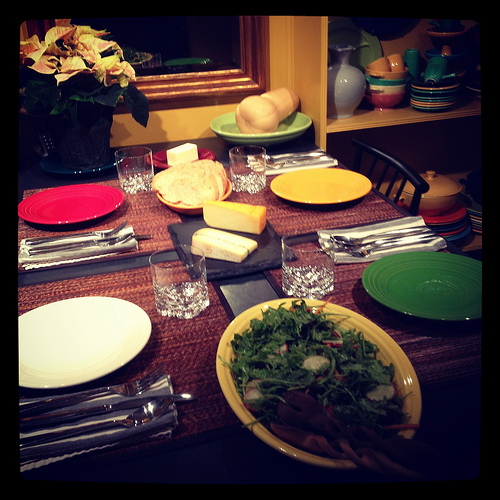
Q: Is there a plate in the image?
A: Yes, there is a plate.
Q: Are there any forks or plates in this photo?
A: Yes, there is a plate.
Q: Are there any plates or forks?
A: Yes, there is a plate.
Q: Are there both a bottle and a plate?
A: No, there is a plate but no bottles.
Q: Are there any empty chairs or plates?
A: Yes, there is an empty plate.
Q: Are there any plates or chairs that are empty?
A: Yes, the plate is empty.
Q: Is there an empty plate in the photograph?
A: Yes, there is an empty plate.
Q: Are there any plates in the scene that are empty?
A: Yes, there is a plate that is empty.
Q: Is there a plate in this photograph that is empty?
A: Yes, there is a plate that is empty.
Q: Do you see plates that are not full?
A: Yes, there is a empty plate.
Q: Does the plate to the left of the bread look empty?
A: Yes, the plate is empty.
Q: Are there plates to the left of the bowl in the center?
A: Yes, there is a plate to the left of the bowl.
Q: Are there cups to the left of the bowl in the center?
A: No, there is a plate to the left of the bowl.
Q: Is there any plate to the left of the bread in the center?
A: Yes, there is a plate to the left of the bread.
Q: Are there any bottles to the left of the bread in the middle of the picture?
A: No, there is a plate to the left of the bread.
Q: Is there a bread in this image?
A: Yes, there is a bread.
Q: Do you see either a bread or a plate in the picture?
A: Yes, there is a bread.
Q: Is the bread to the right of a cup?
A: No, the bread is to the right of the plate.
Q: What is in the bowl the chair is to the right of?
A: The bread is in the bowl.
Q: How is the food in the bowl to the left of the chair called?
A: The food is a bread.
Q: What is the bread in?
A: The bread is in the bowl.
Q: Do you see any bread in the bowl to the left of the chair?
A: Yes, there is a bread in the bowl.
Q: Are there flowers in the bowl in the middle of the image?
A: No, there is a bread in the bowl.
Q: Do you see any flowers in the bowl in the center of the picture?
A: No, there is a bread in the bowl.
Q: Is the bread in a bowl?
A: Yes, the bread is in a bowl.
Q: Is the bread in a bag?
A: No, the bread is in a bowl.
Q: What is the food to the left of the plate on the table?
A: The food is a bread.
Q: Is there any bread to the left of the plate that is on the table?
A: Yes, there is a bread to the left of the plate.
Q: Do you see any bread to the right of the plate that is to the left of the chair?
A: No, the bread is to the left of the plate.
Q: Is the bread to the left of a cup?
A: No, the bread is to the left of the plate.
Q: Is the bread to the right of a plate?
A: No, the bread is to the left of a plate.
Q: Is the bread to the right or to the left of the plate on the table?
A: The bread is to the left of the plate.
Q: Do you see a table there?
A: Yes, there is a table.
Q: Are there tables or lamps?
A: Yes, there is a table.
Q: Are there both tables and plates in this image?
A: Yes, there are both a table and a plate.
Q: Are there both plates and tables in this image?
A: Yes, there are both a table and a plate.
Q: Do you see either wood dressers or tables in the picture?
A: Yes, there is a wood table.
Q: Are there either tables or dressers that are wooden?
A: Yes, the table is wooden.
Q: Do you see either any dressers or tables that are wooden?
A: Yes, the table is wooden.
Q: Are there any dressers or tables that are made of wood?
A: Yes, the table is made of wood.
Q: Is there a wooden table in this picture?
A: Yes, there is a wood table.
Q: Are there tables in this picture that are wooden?
A: Yes, there is a table that is wooden.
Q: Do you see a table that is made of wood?
A: Yes, there is a table that is made of wood.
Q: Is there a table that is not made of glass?
A: Yes, there is a table that is made of wood.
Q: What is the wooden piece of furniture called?
A: The piece of furniture is a table.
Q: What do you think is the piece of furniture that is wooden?
A: The piece of furniture is a table.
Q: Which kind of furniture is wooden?
A: The furniture is a table.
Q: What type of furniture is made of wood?
A: The furniture is a table.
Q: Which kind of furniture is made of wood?
A: The furniture is a table.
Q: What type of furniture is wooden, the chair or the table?
A: The table is wooden.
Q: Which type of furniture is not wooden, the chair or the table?
A: The chair is not wooden.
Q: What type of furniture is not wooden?
A: The furniture is a chair.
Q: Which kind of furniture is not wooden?
A: The furniture is a chair.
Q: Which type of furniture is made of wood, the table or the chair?
A: The table is made of wood.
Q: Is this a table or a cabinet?
A: This is a table.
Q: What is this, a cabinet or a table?
A: This is a table.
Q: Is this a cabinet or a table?
A: This is a table.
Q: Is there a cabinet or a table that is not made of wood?
A: No, there is a table but it is made of wood.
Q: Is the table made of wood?
A: Yes, the table is made of wood.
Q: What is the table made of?
A: The table is made of wood.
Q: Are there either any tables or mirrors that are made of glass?
A: No, there is a table but it is made of wood.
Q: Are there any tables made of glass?
A: No, there is a table but it is made of wood.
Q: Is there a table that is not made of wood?
A: No, there is a table but it is made of wood.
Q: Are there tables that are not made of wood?
A: No, there is a table but it is made of wood.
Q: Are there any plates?
A: Yes, there is a plate.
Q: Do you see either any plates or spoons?
A: Yes, there is a plate.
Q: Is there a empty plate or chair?
A: Yes, there is an empty plate.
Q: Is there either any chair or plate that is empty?
A: Yes, the plate is empty.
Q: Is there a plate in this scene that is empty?
A: Yes, there is an empty plate.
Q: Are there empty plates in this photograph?
A: Yes, there is an empty plate.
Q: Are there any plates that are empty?
A: Yes, there is an empty plate.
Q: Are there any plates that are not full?
A: Yes, there is a empty plate.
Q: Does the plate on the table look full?
A: No, the plate is empty.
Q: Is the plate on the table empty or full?
A: The plate is empty.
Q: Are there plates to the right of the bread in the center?
A: Yes, there is a plate to the right of the bread.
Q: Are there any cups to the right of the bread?
A: No, there is a plate to the right of the bread.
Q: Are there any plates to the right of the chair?
A: No, the plate is to the left of the chair.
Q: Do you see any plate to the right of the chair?
A: No, the plate is to the left of the chair.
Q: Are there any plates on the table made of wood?
A: Yes, there is a plate on the table.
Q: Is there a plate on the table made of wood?
A: Yes, there is a plate on the table.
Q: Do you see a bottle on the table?
A: No, there is a plate on the table.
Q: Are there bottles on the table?
A: No, there is a plate on the table.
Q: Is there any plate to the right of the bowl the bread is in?
A: Yes, there is a plate to the right of the bowl.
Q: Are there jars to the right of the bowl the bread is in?
A: No, there is a plate to the right of the bowl.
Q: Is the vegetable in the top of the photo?
A: Yes, the vegetable is in the top of the image.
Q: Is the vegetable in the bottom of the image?
A: No, the vegetable is in the top of the image.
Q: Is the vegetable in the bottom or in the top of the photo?
A: The vegetable is in the top of the image.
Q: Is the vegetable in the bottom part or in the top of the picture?
A: The vegetable is in the top of the image.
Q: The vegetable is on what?
A: The vegetable is on the table.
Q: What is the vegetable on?
A: The vegetable is on the table.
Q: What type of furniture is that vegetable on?
A: The vegetable is on the table.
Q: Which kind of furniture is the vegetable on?
A: The vegetable is on the table.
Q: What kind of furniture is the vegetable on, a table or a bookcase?
A: The vegetable is on a table.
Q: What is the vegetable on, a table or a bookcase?
A: The vegetable is on a table.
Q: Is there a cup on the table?
A: No, there is a vegetable on the table.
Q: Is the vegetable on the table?
A: Yes, the vegetable is on the table.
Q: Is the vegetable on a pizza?
A: No, the vegetable is on the table.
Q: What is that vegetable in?
A: The vegetable is in the bowl.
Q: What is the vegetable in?
A: The vegetable is in the bowl.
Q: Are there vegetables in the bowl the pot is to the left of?
A: Yes, there is a vegetable in the bowl.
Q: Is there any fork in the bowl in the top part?
A: No, there is a vegetable in the bowl.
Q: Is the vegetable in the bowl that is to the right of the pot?
A: Yes, the vegetable is in the bowl.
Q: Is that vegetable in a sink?
A: No, the vegetable is in the bowl.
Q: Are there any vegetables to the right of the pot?
A: Yes, there is a vegetable to the right of the pot.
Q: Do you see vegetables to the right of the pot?
A: Yes, there is a vegetable to the right of the pot.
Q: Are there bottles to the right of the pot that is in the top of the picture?
A: No, there is a vegetable to the right of the pot.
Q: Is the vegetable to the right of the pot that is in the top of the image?
A: Yes, the vegetable is to the right of the pot.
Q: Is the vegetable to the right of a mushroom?
A: No, the vegetable is to the right of the pot.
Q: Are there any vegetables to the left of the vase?
A: Yes, there is a vegetable to the left of the vase.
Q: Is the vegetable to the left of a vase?
A: Yes, the vegetable is to the left of a vase.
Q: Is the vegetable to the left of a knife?
A: No, the vegetable is to the left of a vase.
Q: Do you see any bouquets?
A: No, there are no bouquets.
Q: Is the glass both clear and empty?
A: Yes, the glass is clear and empty.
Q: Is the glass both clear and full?
A: No, the glass is clear but empty.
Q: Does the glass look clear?
A: Yes, the glass is clear.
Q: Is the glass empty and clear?
A: Yes, the glass is empty and clear.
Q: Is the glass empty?
A: Yes, the glass is empty.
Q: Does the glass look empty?
A: Yes, the glass is empty.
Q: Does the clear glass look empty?
A: Yes, the glass is empty.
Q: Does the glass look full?
A: No, the glass is empty.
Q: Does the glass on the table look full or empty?
A: The glass is empty.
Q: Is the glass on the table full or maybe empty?
A: The glass is empty.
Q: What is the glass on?
A: The glass is on the table.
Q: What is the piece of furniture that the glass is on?
A: The piece of furniture is a table.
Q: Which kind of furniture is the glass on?
A: The glass is on the table.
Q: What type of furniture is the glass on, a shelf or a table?
A: The glass is on a table.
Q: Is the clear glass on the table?
A: Yes, the glass is on the table.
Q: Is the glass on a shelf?
A: No, the glass is on the table.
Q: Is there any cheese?
A: Yes, there is cheese.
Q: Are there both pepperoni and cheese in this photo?
A: No, there is cheese but no pepperoni.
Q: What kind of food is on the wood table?
A: The food is cheese.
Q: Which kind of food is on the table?
A: The food is cheese.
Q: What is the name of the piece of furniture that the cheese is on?
A: The piece of furniture is a table.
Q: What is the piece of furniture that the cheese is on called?
A: The piece of furniture is a table.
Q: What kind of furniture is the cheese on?
A: The cheese is on the table.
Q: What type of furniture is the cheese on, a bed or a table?
A: The cheese is on a table.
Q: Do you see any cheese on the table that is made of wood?
A: Yes, there is cheese on the table.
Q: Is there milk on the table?
A: No, there is cheese on the table.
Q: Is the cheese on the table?
A: Yes, the cheese is on the table.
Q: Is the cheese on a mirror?
A: No, the cheese is on the table.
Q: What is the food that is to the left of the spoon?
A: The food is cheese.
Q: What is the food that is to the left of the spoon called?
A: The food is cheese.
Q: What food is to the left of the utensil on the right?
A: The food is cheese.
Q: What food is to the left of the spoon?
A: The food is cheese.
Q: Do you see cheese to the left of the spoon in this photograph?
A: Yes, there is cheese to the left of the spoon.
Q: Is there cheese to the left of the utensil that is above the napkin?
A: Yes, there is cheese to the left of the spoon.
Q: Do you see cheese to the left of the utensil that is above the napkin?
A: Yes, there is cheese to the left of the spoon.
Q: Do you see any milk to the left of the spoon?
A: No, there is cheese to the left of the spoon.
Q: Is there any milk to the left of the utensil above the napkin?
A: No, there is cheese to the left of the spoon.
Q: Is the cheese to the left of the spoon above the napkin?
A: Yes, the cheese is to the left of the spoon.